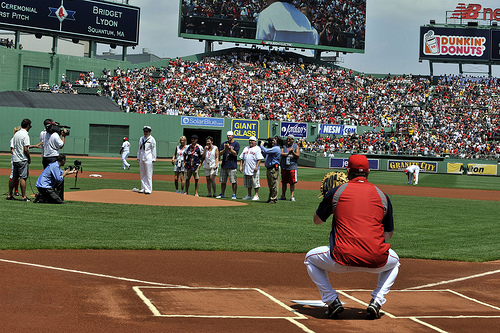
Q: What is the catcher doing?
A: Crouching.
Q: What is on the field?
A: A crowd.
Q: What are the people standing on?
A: Lush green grass.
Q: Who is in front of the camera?
A: The Audience.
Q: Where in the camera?
A: Pitchers mound.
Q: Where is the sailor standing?
A: Pitchers mound.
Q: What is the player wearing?
A: Baseball glove.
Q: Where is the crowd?
A: Baseball stadium.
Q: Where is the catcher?
A: Home plate.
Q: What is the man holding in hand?
A: Glove.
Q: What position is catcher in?
A: Crouching.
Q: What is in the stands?
A: Fans.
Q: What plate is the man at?
A: Home plate.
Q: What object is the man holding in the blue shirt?
A: Videocamera.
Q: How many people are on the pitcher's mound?
A: One.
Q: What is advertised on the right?
A: Dunkin Donuts.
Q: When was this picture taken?
A: During the day.